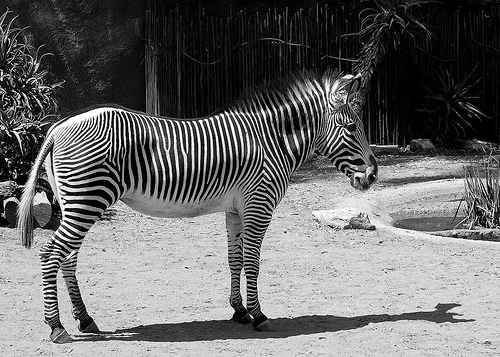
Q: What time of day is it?
A: Day time.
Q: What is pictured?
A: Zebra.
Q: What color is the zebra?
A: Black and white.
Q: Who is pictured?
A: No one.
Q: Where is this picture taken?
A: Zoo.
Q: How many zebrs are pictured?
A: One.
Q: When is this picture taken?
A: While visiting.